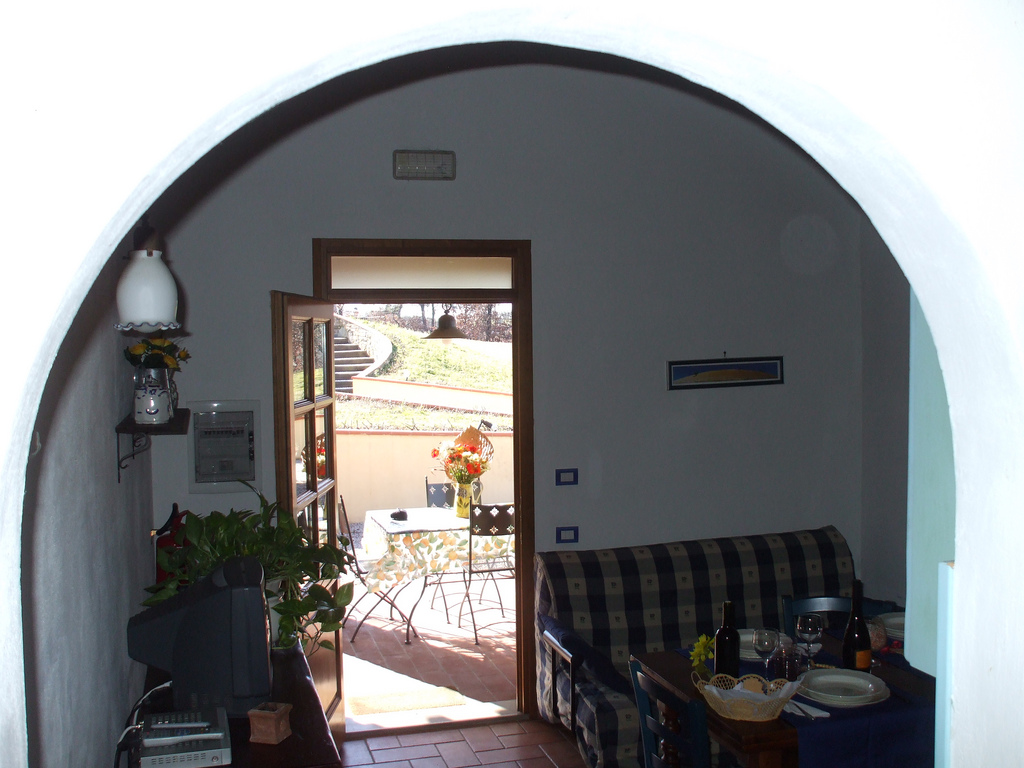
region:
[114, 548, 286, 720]
The side of a television set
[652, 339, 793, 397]
A framed rectangular painting hanging on wall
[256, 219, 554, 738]
A door is wide open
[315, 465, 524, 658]
Chairs around a table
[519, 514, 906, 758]
A sofa against the wall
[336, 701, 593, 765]
Brown tiles on the floor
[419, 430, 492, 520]
Flowers in a vase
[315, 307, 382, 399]
A set of stairs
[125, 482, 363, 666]
The leaves are colored green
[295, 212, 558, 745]
the door is open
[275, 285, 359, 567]
a wood and glass door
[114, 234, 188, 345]
a white lamp shade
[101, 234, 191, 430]
a lamp on a shelf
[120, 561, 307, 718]
a small black television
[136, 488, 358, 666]
a green ivy plant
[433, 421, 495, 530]
orange flowers on a table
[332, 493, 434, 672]
a metal chair on the porch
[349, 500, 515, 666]
table and chairs on the porch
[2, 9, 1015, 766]
an arched doorway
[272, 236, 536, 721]
a doorway with a multi-paneled door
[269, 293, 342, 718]
a door with several glass pane windows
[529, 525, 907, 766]
a tartan-patterned sofa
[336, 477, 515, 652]
a patio dinette set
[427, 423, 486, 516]
a vase of orange flowers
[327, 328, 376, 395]
a cement staircase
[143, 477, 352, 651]
a leafy green potted plant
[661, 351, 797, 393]
Framed picture hanging on the wall.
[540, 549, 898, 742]
Blue and tan colored couch in room.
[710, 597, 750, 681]
Bottle of wine sitting on table.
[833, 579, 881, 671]
Bottle of wine sitting on table.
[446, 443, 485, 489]
Red flowers in vase outside on table.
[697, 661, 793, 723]
Light brown basket sitting on table.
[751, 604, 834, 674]
Empty glasses of wine on table.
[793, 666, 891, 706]
White plate sitting on table.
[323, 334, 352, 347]
step is made of cement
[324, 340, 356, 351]
step is made of cement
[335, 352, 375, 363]
step is made of cement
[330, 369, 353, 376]
step is made of cement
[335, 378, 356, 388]
step is made of cement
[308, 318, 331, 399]
glass is clean and clear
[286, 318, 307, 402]
glass is clean and clear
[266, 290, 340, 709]
the door has panes of glass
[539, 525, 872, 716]
a cover on a couch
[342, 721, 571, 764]
red bricks on the floor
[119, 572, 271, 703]
the television is black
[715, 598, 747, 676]
a black wine bottle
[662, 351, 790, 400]
framed picture on the wall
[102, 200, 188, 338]
the lamp has a white shade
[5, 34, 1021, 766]
the doorway is arched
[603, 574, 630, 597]
A square on the couch.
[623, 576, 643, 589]
A square on the couch.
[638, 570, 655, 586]
A square on the couch.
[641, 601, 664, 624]
A square on the couch.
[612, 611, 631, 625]
A square on the couch.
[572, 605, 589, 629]
A square on the couch.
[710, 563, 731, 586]
A square on the couch.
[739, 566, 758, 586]
A square on the couch.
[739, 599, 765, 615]
A square on the couch.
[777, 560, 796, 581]
A square on the couch.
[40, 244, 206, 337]
the light is white